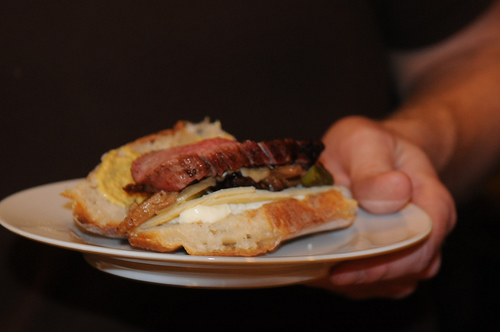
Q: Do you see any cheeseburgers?
A: No, there are no cheeseburgers.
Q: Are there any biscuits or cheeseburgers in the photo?
A: No, there are no cheeseburgers or biscuits.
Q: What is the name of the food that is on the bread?
A: The food is an egg.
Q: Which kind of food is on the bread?
A: The food is an egg.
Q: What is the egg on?
A: The egg is on the bread.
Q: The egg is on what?
A: The egg is on the bread.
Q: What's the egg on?
A: The egg is on the bread.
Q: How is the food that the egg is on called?
A: The food is a bread.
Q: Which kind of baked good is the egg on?
A: The egg is on the bread.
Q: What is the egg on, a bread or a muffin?
A: The egg is on a bread.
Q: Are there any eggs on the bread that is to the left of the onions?
A: Yes, there is an egg on the bread.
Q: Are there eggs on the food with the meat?
A: Yes, there is an egg on the bread.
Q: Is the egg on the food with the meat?
A: Yes, the egg is on the bread.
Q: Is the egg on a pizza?
A: No, the egg is on the bread.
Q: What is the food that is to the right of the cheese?
A: The food is an egg.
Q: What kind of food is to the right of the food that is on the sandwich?
A: The food is an egg.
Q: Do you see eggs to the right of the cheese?
A: Yes, there is an egg to the right of the cheese.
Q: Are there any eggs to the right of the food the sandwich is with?
A: Yes, there is an egg to the right of the cheese.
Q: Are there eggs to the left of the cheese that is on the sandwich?
A: No, the egg is to the right of the cheese.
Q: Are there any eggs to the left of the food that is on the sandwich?
A: No, the egg is to the right of the cheese.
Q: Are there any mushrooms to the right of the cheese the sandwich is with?
A: No, there is an egg to the right of the cheese.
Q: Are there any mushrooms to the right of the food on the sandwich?
A: No, there is an egg to the right of the cheese.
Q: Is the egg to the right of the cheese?
A: Yes, the egg is to the right of the cheese.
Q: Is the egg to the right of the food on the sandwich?
A: Yes, the egg is to the right of the cheese.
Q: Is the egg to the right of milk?
A: No, the egg is to the right of the cheese.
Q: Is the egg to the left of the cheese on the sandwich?
A: No, the egg is to the right of the cheese.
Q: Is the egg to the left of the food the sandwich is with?
A: No, the egg is to the right of the cheese.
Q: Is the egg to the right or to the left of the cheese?
A: The egg is to the right of the cheese.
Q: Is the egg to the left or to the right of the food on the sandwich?
A: The egg is to the right of the cheese.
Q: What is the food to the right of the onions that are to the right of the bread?
A: The food is an egg.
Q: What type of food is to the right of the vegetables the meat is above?
A: The food is an egg.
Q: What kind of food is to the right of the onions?
A: The food is an egg.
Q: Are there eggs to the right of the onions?
A: Yes, there is an egg to the right of the onions.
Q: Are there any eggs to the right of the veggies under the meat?
A: Yes, there is an egg to the right of the onions.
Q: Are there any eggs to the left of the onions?
A: No, the egg is to the right of the onions.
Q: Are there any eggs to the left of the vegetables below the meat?
A: No, the egg is to the right of the onions.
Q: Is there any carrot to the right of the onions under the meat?
A: No, there is an egg to the right of the onions.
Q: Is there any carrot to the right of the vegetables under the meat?
A: No, there is an egg to the right of the onions.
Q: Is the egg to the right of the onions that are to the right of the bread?
A: Yes, the egg is to the right of the onions.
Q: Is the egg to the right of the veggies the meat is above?
A: Yes, the egg is to the right of the onions.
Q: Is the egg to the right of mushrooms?
A: No, the egg is to the right of the onions.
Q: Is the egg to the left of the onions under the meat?
A: No, the egg is to the right of the onions.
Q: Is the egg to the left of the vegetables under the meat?
A: No, the egg is to the right of the onions.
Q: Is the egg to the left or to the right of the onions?
A: The egg is to the right of the onions.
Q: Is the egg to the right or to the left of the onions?
A: The egg is to the right of the onions.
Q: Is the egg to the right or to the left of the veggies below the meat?
A: The egg is to the right of the onions.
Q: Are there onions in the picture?
A: Yes, there are onions.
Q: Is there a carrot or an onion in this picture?
A: Yes, there are onions.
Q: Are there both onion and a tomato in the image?
A: No, there are onions but no tomatoes.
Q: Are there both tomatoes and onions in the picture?
A: No, there are onions but no tomatoes.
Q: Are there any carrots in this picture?
A: No, there are no carrots.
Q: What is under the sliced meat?
A: The onions are under the meat.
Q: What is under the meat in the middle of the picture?
A: The onions are under the meat.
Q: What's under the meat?
A: The onions are under the meat.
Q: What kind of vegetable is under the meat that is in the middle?
A: The vegetables are onions.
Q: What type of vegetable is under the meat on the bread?
A: The vegetables are onions.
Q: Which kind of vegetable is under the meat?
A: The vegetables are onions.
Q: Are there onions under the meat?
A: Yes, there are onions under the meat.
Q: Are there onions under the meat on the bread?
A: Yes, there are onions under the meat.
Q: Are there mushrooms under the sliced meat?
A: No, there are onions under the meat.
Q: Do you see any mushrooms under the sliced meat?
A: No, there are onions under the meat.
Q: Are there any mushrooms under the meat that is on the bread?
A: No, there are onions under the meat.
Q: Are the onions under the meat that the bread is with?
A: Yes, the onions are under the meat.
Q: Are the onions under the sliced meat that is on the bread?
A: Yes, the onions are under the meat.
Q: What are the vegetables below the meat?
A: The vegetables are onions.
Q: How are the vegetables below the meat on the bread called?
A: The vegetables are onions.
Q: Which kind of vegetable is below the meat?
A: The vegetables are onions.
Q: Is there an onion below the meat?
A: Yes, there are onions below the meat.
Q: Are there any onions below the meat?
A: Yes, there are onions below the meat.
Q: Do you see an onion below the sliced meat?
A: Yes, there are onions below the meat.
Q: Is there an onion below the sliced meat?
A: Yes, there are onions below the meat.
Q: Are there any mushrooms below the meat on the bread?
A: No, there are onions below the meat.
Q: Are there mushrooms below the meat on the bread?
A: No, there are onions below the meat.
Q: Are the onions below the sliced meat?
A: Yes, the onions are below the meat.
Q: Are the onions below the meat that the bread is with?
A: Yes, the onions are below the meat.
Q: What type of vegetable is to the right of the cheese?
A: The vegetables are onions.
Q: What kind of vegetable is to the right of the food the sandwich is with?
A: The vegetables are onions.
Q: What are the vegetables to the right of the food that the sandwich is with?
A: The vegetables are onions.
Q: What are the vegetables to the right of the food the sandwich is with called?
A: The vegetables are onions.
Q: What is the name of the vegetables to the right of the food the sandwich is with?
A: The vegetables are onions.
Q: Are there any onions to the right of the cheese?
A: Yes, there are onions to the right of the cheese.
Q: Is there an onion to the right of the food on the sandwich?
A: Yes, there are onions to the right of the cheese.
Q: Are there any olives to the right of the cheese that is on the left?
A: No, there are onions to the right of the cheese.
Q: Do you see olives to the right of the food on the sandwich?
A: No, there are onions to the right of the cheese.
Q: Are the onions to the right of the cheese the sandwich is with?
A: Yes, the onions are to the right of the cheese.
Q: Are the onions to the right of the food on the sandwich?
A: Yes, the onions are to the right of the cheese.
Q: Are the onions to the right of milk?
A: No, the onions are to the right of the cheese.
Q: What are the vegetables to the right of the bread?
A: The vegetables are onions.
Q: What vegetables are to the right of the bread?
A: The vegetables are onions.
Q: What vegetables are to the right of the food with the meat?
A: The vegetables are onions.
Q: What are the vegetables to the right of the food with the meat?
A: The vegetables are onions.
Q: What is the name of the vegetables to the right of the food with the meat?
A: The vegetables are onions.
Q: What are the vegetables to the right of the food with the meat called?
A: The vegetables are onions.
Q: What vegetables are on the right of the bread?
A: The vegetables are onions.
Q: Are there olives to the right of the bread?
A: No, there are onions to the right of the bread.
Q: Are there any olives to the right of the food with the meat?
A: No, there are onions to the right of the bread.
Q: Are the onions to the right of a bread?
A: Yes, the onions are to the right of a bread.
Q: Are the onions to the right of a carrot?
A: No, the onions are to the right of a bread.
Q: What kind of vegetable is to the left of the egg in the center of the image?
A: The vegetables are onions.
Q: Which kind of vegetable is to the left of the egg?
A: The vegetables are onions.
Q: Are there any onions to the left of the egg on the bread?
A: Yes, there are onions to the left of the egg.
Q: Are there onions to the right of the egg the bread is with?
A: No, the onions are to the left of the egg.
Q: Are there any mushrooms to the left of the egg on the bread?
A: No, there are onions to the left of the egg.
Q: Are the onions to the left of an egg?
A: Yes, the onions are to the left of an egg.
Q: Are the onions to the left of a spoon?
A: No, the onions are to the left of an egg.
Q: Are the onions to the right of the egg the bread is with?
A: No, the onions are to the left of the egg.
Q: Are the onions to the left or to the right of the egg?
A: The onions are to the left of the egg.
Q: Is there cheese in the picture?
A: Yes, there is cheese.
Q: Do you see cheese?
A: Yes, there is cheese.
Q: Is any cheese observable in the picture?
A: Yes, there is cheese.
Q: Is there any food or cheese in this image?
A: Yes, there is cheese.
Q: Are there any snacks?
A: No, there are no snacks.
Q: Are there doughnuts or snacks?
A: No, there are no snacks or doughnuts.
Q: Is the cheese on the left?
A: Yes, the cheese is on the left of the image.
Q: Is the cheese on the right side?
A: No, the cheese is on the left of the image.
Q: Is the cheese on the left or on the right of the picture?
A: The cheese is on the left of the image.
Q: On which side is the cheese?
A: The cheese is on the left of the image.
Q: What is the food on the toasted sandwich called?
A: The food is cheese.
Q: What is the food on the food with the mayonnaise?
A: The food is cheese.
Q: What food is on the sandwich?
A: The food is cheese.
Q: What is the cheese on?
A: The cheese is on the sandwich.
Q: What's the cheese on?
A: The cheese is on the sandwich.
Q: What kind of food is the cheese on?
A: The cheese is on the sandwich.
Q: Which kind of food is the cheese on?
A: The cheese is on the sandwich.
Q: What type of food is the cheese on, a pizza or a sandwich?
A: The cheese is on a sandwich.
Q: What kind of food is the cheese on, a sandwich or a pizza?
A: The cheese is on a sandwich.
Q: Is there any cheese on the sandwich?
A: Yes, there is cheese on the sandwich.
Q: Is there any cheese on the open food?
A: Yes, there is cheese on the sandwich.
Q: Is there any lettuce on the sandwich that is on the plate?
A: No, there is cheese on the sandwich.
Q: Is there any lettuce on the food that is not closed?
A: No, there is cheese on the sandwich.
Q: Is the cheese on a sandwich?
A: Yes, the cheese is on a sandwich.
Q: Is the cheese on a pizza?
A: No, the cheese is on a sandwich.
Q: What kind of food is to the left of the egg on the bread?
A: The food is cheese.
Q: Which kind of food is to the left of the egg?
A: The food is cheese.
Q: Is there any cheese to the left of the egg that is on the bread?
A: Yes, there is cheese to the left of the egg.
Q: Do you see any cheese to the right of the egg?
A: No, the cheese is to the left of the egg.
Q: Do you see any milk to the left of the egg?
A: No, there is cheese to the left of the egg.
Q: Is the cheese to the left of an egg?
A: Yes, the cheese is to the left of an egg.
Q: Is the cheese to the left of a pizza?
A: No, the cheese is to the left of an egg.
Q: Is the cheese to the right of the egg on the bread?
A: No, the cheese is to the left of the egg.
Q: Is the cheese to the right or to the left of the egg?
A: The cheese is to the left of the egg.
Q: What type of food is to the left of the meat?
A: The food is cheese.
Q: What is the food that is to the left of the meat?
A: The food is cheese.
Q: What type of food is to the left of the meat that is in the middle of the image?
A: The food is cheese.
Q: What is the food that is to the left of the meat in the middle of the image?
A: The food is cheese.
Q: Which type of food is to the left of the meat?
A: The food is cheese.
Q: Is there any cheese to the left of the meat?
A: Yes, there is cheese to the left of the meat.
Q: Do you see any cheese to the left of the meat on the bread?
A: Yes, there is cheese to the left of the meat.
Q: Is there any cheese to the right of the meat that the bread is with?
A: No, the cheese is to the left of the meat.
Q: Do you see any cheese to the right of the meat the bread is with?
A: No, the cheese is to the left of the meat.